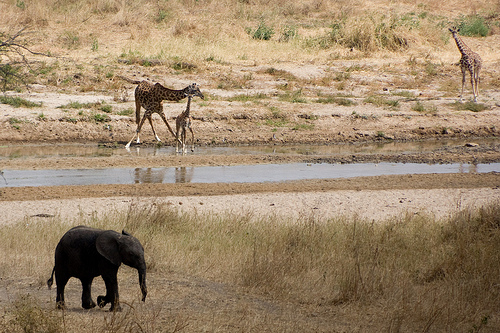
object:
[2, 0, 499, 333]
valley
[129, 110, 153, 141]
leg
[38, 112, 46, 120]
grass clump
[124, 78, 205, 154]
giraffe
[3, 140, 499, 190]
floor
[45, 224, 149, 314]
elephant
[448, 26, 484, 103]
giraffe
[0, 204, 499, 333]
grass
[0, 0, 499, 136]
grass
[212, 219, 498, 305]
branches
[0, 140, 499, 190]
water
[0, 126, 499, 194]
hole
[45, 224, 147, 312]
animals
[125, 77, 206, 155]
animals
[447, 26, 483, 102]
animals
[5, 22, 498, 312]
wild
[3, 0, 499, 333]
savanna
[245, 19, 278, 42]
grass